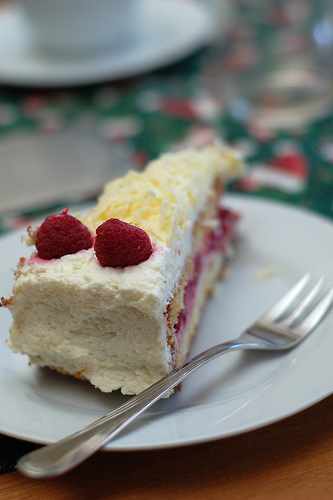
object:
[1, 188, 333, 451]
dish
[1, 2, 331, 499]
table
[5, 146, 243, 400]
cake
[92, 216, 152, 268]
berries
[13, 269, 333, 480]
fork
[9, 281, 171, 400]
frosting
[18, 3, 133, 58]
cup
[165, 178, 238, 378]
filling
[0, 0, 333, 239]
tablecloth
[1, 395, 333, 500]
shadow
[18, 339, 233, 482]
handle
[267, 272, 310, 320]
tines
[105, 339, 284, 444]
shadow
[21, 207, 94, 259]
raspberry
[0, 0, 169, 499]
left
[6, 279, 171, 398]
back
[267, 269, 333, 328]
light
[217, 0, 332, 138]
glass